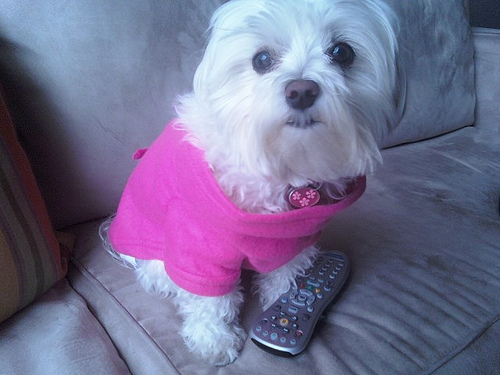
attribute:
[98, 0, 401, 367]
dog — small, white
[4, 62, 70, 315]
pillow — striped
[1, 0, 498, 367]
couch — brown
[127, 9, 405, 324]
dog — little, white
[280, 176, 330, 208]
collar — pink, dog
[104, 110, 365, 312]
dress — pink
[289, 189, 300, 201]
flower — pink 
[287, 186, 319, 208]
tag — pink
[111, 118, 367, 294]
shirt — pink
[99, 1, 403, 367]
white dog — fluffy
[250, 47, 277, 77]
eye — dog's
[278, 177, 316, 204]
tag — pink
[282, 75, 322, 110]
nose — brown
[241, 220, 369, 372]
remote — silver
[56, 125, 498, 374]
cushion — wrinkled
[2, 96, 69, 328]
pillow — striped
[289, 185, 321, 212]
collar — round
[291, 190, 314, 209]
flowers — purple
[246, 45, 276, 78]
eye — black, color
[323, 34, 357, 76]
eye — color, black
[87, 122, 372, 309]
dog clothing — hot pink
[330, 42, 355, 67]
eye — brown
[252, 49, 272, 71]
eye — brown